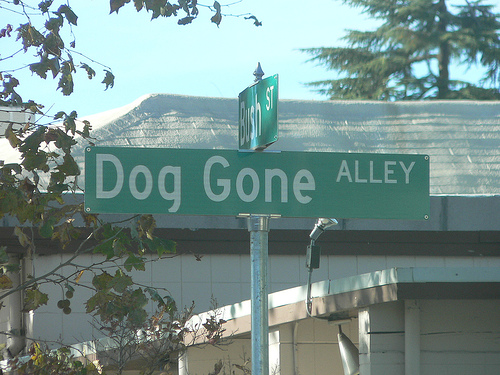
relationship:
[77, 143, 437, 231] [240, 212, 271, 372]
sign on pole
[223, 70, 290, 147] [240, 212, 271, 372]
sign on pole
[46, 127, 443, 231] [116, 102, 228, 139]
building roof with shingles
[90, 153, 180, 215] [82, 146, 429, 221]
word on sign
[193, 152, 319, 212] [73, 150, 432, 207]
gone on sign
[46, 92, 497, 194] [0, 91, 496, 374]
building roof of building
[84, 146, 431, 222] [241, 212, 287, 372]
sign on pole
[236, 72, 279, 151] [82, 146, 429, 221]
sign on top of sign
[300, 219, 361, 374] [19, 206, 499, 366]
lights on side of building